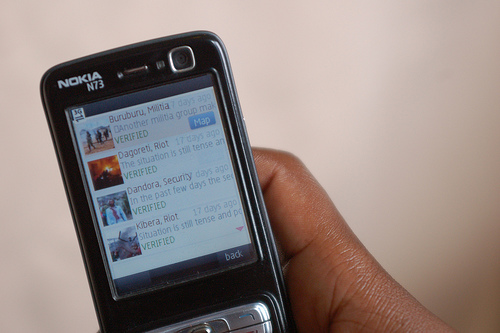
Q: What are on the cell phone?
A: Four pictures.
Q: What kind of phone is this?
A: Nokia N73.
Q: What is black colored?
A: Cell phone.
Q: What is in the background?
A: A white wall.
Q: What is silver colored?
A: The buttons.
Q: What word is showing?
A: Buruburu, Militia.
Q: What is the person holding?
A: Cell phone.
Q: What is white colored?
A: The background.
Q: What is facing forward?
A: The person's hand.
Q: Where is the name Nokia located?
A: On upper left corner of phone.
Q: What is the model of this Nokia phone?
A: N73.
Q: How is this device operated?
A: Buttons.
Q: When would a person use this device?
A: Phone call.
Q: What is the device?
A: Cell phone.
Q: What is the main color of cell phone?
A: Black.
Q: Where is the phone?
A: Hand.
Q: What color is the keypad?
A: Silver.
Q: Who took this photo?
A: Photographer.